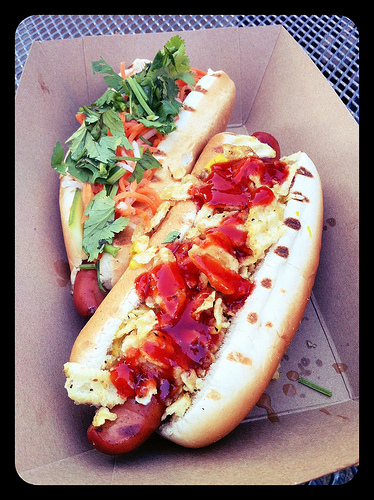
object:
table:
[13, 13, 363, 491]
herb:
[294, 371, 337, 398]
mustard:
[127, 244, 159, 272]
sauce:
[155, 268, 178, 291]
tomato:
[111, 191, 157, 217]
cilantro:
[48, 33, 197, 296]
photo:
[0, 0, 374, 500]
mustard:
[204, 153, 231, 174]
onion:
[131, 139, 142, 159]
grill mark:
[116, 423, 142, 440]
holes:
[68, 26, 79, 36]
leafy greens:
[125, 146, 165, 186]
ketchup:
[186, 154, 289, 225]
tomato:
[187, 166, 274, 208]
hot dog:
[58, 125, 330, 457]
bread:
[63, 128, 327, 456]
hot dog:
[56, 57, 239, 321]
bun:
[55, 52, 239, 302]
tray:
[14, 22, 361, 486]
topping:
[164, 250, 223, 333]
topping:
[100, 69, 159, 158]